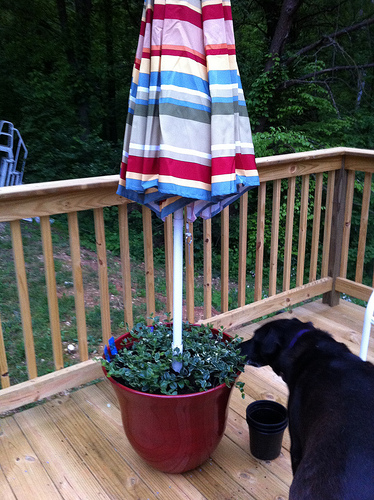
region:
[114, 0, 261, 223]
Colorful umbrella sticking out of a red flower pot.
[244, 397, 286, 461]
Three small black pots stacked inside each other.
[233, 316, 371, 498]
Black dog with blue collar on.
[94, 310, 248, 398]
Green leaves and blue flowers coming out of a red flower pot.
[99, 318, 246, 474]
Shiny red flower pot holding flowers.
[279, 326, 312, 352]
Blue collar on a black dog.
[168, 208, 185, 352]
White pole that holds up an umbrella.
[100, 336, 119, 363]
Two long blue flowers on the left side of the pot.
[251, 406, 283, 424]
Dark round middle of a black pot.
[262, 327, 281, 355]
A black dogs left ear.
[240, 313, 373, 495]
a dog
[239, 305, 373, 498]
a black dog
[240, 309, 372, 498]
a black dog with a blue collar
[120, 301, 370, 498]
the dog sniffs at the pot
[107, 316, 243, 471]
a red pot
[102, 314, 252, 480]
plants are in the red pot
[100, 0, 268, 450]
an umbrella is in the red pot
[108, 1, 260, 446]
a striped umbrella is in the red pot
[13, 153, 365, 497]
a deck with rails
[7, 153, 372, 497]
a wood deck with a railing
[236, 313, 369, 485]
Black dog with a blue collar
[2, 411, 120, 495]
Wooden plank deck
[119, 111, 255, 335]
Red, white, grey and blue umbrella anchored in flower pot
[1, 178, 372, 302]
Wooden railing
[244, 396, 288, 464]
Three empty planting pots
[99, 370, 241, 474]
Red ceramic flower pot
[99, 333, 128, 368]
Blue flowers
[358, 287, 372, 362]
Leg of a deck chair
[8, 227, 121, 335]
Poorly maintained lawn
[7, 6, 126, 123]
Forest-like area beyond the yard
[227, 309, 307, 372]
the head of a dog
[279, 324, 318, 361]
a blue collar on the dog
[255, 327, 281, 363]
the ear of a dog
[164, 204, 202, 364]
a white umbrella pole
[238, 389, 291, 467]
a black pot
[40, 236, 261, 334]
a brown patch of dirt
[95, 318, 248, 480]
a red planter pot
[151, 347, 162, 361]
a small green leaf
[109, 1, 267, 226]
a striped umbrella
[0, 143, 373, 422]
a wooden fence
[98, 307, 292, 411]
dog with nose in planter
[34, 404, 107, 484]
wood floor of deck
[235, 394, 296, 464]
empty black container on deck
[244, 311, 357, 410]
black dog with blue collar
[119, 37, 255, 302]
closed umbrella on pole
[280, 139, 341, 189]
wood rail on deck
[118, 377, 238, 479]
shiny red planter on deck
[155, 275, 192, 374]
white pole in planter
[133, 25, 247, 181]
stripes on closed umbrella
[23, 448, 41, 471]
knot in wood grain